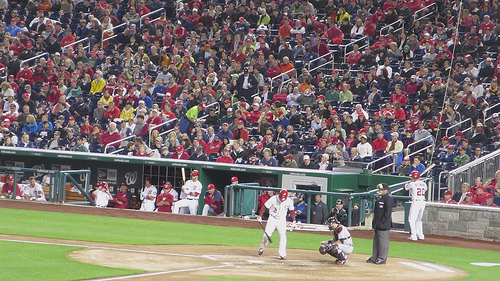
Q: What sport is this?
A: Baseball.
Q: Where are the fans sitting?
A: Bleachers.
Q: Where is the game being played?
A: Baseball field.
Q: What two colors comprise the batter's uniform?
A: Red and white.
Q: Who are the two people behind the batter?
A: Catcher and umpire.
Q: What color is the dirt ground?
A: Brown.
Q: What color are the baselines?
A: White.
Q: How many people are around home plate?
A: Three.